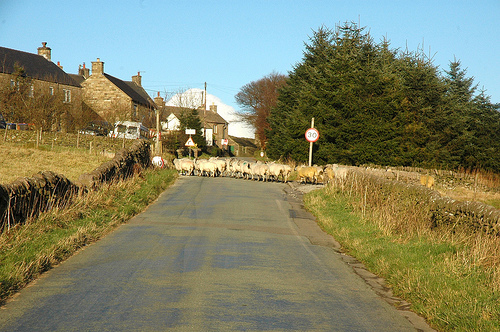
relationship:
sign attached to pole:
[304, 121, 313, 146] [306, 116, 316, 169]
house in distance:
[156, 92, 231, 157] [30, 15, 499, 190]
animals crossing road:
[150, 155, 351, 185] [195, 168, 230, 209]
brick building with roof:
[80, 56, 161, 138] [101, 72, 146, 105]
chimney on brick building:
[87, 55, 105, 73] [80, 57, 160, 139]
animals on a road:
[150, 155, 351, 185] [9, 172, 426, 329]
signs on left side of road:
[148, 129, 230, 174] [1, 149, 438, 330]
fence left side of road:
[1, 162, 136, 262] [9, 172, 426, 329]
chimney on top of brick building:
[128, 69, 144, 88] [80, 57, 160, 139]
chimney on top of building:
[36, 40, 50, 61] [0, 41, 83, 134]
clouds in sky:
[157, 61, 263, 113] [0, 0, 500, 135]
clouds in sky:
[61, 0, 131, 61] [0, 2, 499, 100]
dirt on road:
[209, 213, 261, 270] [9, 172, 426, 329]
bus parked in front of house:
[106, 121, 150, 140] [78, 64, 153, 139]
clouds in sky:
[160, 6, 280, 58] [0, 0, 500, 135]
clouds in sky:
[171, 84, 268, 148] [5, 5, 497, 124]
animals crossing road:
[169, 150, 396, 188] [1, 149, 438, 330]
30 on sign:
[306, 132, 316, 138] [304, 126, 318, 142]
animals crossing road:
[150, 155, 351, 185] [9, 172, 426, 329]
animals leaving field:
[150, 155, 351, 185] [303, 167, 494, 329]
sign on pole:
[305, 127, 320, 142] [307, 116, 317, 168]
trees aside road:
[269, 27, 498, 179] [9, 172, 426, 329]